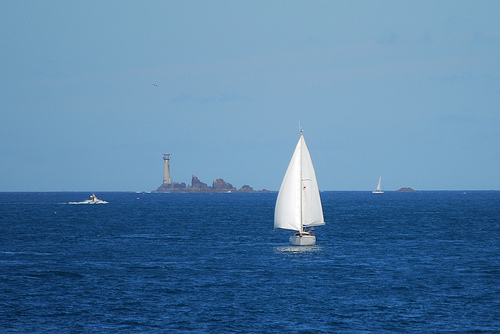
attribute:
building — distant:
[215, 177, 232, 189]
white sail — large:
[268, 132, 325, 233]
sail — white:
[302, 116, 326, 226]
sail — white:
[272, 134, 300, 230]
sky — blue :
[1, 6, 453, 172]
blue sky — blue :
[2, 0, 497, 190]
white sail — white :
[273, 133, 325, 230]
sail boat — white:
[270, 133, 329, 245]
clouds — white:
[190, 15, 386, 86]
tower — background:
[158, 145, 175, 191]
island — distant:
[141, 151, 276, 211]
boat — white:
[266, 119, 328, 251]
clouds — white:
[257, 80, 333, 117]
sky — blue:
[22, 25, 114, 120]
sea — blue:
[2, 185, 499, 331]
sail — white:
[273, 130, 327, 234]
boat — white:
[268, 130, 330, 246]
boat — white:
[370, 167, 387, 195]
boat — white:
[79, 187, 107, 202]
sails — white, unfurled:
[273, 123, 328, 228]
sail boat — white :
[234, 123, 369, 271]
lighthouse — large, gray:
[154, 152, 177, 187]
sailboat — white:
[370, 175, 387, 195]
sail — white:
[298, 132, 325, 229]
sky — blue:
[5, 4, 493, 127]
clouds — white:
[167, 38, 242, 97]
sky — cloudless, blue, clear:
[2, 3, 499, 193]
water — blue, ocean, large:
[4, 187, 498, 330]